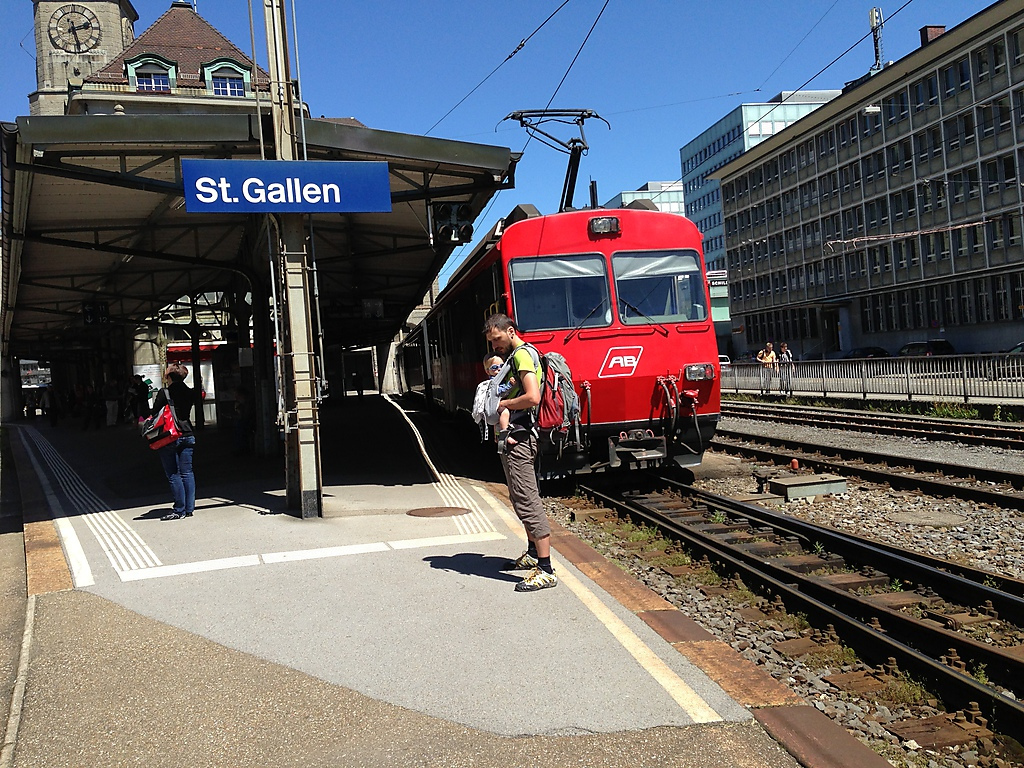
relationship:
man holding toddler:
[484, 316, 557, 593] [474, 351, 523, 447]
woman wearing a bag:
[135, 357, 196, 520] [135, 406, 186, 453]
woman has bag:
[135, 357, 196, 520] [135, 406, 186, 453]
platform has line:
[389, 542, 706, 735] [572, 587, 706, 734]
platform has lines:
[389, 578, 663, 734] [186, 528, 409, 574]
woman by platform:
[135, 357, 196, 520] [135, 349, 483, 704]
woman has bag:
[136, 357, 198, 481] [136, 400, 178, 452]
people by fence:
[751, 330, 802, 389] [790, 354, 930, 402]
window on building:
[969, 38, 1005, 68] [675, 14, 1015, 368]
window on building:
[122, 52, 177, 87] [19, 3, 302, 125]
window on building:
[199, 58, 264, 109] [35, 1, 264, 109]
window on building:
[994, 202, 1020, 251] [704, 65, 1019, 344]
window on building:
[963, 216, 986, 252] [669, 71, 1021, 329]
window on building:
[882, 229, 915, 274] [675, 14, 1015, 368]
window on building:
[897, 222, 926, 265] [669, 71, 1021, 329]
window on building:
[776, 215, 809, 253] [694, 95, 1017, 368]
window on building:
[827, 204, 847, 231] [694, 95, 1017, 368]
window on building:
[862, 191, 895, 230] [675, 58, 983, 333]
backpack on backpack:
[541, 351, 579, 441] [540, 351, 578, 441]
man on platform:
[468, 315, 575, 591] [12, 393, 745, 763]